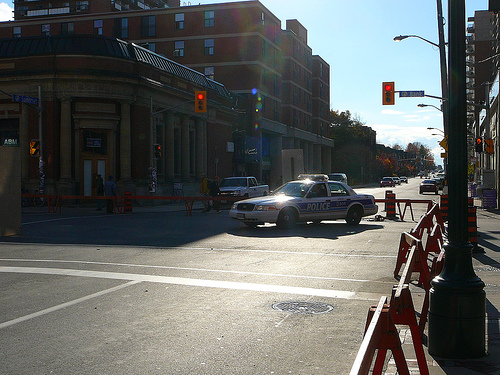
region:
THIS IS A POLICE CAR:
[226, 169, 386, 236]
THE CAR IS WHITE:
[225, 165, 382, 231]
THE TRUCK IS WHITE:
[211, 170, 278, 219]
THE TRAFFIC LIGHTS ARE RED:
[175, 75, 400, 111]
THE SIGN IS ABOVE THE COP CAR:
[393, 86, 433, 107]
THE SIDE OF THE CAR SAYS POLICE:
[304, 198, 335, 216]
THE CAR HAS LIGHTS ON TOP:
[283, 171, 331, 183]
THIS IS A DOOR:
[78, 140, 113, 207]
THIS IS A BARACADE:
[304, 186, 464, 373]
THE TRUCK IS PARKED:
[219, 173, 270, 214]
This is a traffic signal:
[192, 88, 209, 113]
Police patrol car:
[229, 173, 377, 235]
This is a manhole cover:
[268, 295, 337, 318]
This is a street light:
[388, 30, 447, 50]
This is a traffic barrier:
[347, 296, 410, 373]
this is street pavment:
[3, 234, 265, 374]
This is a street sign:
[398, 89, 427, 100]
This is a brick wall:
[218, 11, 259, 28]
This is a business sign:
[83, 135, 105, 153]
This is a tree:
[408, 145, 428, 159]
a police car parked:
[232, 174, 378, 229]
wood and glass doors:
[79, 148, 108, 206]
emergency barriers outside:
[356, 197, 448, 374]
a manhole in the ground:
[272, 298, 334, 314]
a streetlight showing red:
[192, 90, 206, 112]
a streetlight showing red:
[381, 80, 393, 105]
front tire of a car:
[273, 208, 296, 231]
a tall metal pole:
[430, 0, 486, 352]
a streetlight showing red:
[472, 136, 487, 152]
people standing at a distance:
[87, 175, 119, 210]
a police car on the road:
[226, 153, 391, 245]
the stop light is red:
[368, 67, 400, 123]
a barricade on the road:
[338, 185, 455, 373]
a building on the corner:
[3, 28, 242, 243]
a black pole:
[420, 2, 490, 362]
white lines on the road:
[1, 253, 398, 365]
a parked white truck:
[213, 166, 281, 211]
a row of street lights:
[389, 28, 454, 143]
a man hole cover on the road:
[267, 288, 341, 328]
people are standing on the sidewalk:
[68, 161, 135, 216]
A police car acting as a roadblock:
[231, 173, 378, 238]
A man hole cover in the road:
[272, 294, 333, 316]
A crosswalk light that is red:
[475, 136, 483, 153]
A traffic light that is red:
[189, 87, 212, 112]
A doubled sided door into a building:
[76, 157, 111, 204]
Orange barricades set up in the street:
[344, 189, 443, 373]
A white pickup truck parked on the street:
[215, 176, 272, 204]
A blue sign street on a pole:
[399, 86, 425, 102]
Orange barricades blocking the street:
[53, 192, 235, 215]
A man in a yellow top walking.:
[194, 171, 216, 216]